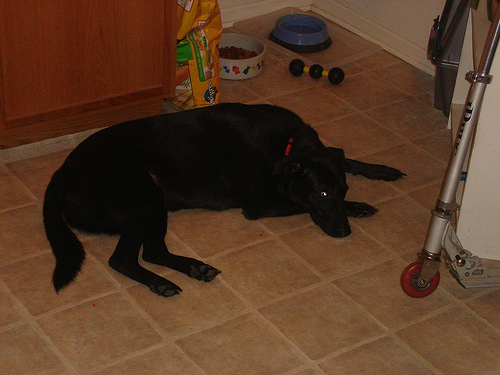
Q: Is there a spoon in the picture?
A: No, there are no spoons.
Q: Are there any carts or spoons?
A: No, there are no spoons or carts.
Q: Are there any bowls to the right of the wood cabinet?
A: Yes, there is a bowl to the right of the cabinet.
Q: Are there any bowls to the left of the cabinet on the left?
A: No, the bowl is to the right of the cabinet.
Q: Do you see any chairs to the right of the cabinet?
A: No, there is a bowl to the right of the cabinet.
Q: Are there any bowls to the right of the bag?
A: Yes, there is a bowl to the right of the bag.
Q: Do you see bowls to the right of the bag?
A: Yes, there is a bowl to the right of the bag.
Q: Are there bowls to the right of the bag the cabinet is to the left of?
A: Yes, there is a bowl to the right of the bag.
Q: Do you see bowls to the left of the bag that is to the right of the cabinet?
A: No, the bowl is to the right of the bag.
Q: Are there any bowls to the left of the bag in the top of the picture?
A: No, the bowl is to the right of the bag.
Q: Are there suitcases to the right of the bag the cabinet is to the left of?
A: No, there is a bowl to the right of the bag.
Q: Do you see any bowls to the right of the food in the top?
A: Yes, there is a bowl to the right of the food.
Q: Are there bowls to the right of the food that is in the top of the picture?
A: Yes, there is a bowl to the right of the food.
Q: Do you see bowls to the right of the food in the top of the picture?
A: Yes, there is a bowl to the right of the food.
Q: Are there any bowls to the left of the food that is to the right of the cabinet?
A: No, the bowl is to the right of the food.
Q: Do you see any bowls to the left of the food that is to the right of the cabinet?
A: No, the bowl is to the right of the food.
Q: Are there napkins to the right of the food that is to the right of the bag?
A: No, there is a bowl to the right of the food.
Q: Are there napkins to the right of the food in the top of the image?
A: No, there is a bowl to the right of the food.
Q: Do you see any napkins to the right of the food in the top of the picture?
A: No, there is a bowl to the right of the food.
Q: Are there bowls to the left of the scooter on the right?
A: Yes, there is a bowl to the left of the scooter.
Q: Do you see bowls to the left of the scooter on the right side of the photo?
A: Yes, there is a bowl to the left of the scooter.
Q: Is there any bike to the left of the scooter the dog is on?
A: No, there is a bowl to the left of the scooter.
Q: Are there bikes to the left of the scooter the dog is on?
A: No, there is a bowl to the left of the scooter.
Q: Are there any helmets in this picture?
A: No, there are no helmets.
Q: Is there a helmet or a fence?
A: No, there are no helmets or fences.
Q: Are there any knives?
A: No, there are no knives.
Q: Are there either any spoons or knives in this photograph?
A: No, there are no knives or spoons.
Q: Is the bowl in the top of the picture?
A: Yes, the bowl is in the top of the image.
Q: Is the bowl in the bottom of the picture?
A: No, the bowl is in the top of the image.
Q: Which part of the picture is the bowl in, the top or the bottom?
A: The bowl is in the top of the image.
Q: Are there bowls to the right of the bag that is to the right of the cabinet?
A: Yes, there is a bowl to the right of the bag.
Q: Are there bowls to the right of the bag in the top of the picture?
A: Yes, there is a bowl to the right of the bag.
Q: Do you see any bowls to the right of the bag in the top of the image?
A: Yes, there is a bowl to the right of the bag.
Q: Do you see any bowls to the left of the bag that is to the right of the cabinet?
A: No, the bowl is to the right of the bag.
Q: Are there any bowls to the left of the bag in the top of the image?
A: No, the bowl is to the right of the bag.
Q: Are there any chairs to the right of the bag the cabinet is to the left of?
A: No, there is a bowl to the right of the bag.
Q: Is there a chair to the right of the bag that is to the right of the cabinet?
A: No, there is a bowl to the right of the bag.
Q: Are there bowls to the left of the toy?
A: Yes, there is a bowl to the left of the toy.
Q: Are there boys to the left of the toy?
A: No, there is a bowl to the left of the toy.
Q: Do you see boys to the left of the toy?
A: No, there is a bowl to the left of the toy.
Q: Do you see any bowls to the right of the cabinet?
A: Yes, there is a bowl to the right of the cabinet.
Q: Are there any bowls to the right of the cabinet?
A: Yes, there is a bowl to the right of the cabinet.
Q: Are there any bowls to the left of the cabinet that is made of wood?
A: No, the bowl is to the right of the cabinet.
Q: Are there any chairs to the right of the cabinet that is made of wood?
A: No, there is a bowl to the right of the cabinet.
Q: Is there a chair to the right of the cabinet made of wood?
A: No, there is a bowl to the right of the cabinet.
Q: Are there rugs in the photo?
A: No, there are no rugs.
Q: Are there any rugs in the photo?
A: No, there are no rugs.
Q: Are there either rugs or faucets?
A: No, there are no rugs or faucets.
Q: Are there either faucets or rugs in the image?
A: No, there are no rugs or faucets.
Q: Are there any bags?
A: Yes, there is a bag.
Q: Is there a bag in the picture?
A: Yes, there is a bag.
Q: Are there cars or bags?
A: Yes, there is a bag.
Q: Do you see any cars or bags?
A: Yes, there is a bag.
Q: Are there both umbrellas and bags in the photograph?
A: No, there is a bag but no umbrellas.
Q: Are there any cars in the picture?
A: No, there are no cars.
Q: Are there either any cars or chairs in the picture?
A: No, there are no cars or chairs.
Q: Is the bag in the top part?
A: Yes, the bag is in the top of the image.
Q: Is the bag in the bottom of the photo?
A: No, the bag is in the top of the image.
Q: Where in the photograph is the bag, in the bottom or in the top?
A: The bag is in the top of the image.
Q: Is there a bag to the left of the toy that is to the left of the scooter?
A: Yes, there is a bag to the left of the toy.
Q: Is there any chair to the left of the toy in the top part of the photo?
A: No, there is a bag to the left of the toy.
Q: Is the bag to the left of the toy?
A: Yes, the bag is to the left of the toy.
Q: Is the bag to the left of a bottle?
A: No, the bag is to the left of the toy.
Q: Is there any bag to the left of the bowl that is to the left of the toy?
A: Yes, there is a bag to the left of the bowl.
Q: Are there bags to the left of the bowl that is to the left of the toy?
A: Yes, there is a bag to the left of the bowl.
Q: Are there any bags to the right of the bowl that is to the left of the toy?
A: No, the bag is to the left of the bowl.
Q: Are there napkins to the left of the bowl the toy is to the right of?
A: No, there is a bag to the left of the bowl.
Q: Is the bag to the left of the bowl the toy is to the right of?
A: Yes, the bag is to the left of the bowl.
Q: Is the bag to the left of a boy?
A: No, the bag is to the left of the bowl.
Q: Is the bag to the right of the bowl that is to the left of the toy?
A: No, the bag is to the left of the bowl.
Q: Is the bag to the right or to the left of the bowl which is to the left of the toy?
A: The bag is to the left of the bowl.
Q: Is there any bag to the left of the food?
A: Yes, there is a bag to the left of the food.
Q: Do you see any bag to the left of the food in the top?
A: Yes, there is a bag to the left of the food.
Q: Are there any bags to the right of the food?
A: No, the bag is to the left of the food.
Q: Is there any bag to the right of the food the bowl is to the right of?
A: No, the bag is to the left of the food.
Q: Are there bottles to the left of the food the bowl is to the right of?
A: No, there is a bag to the left of the food.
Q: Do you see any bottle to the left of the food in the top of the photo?
A: No, there is a bag to the left of the food.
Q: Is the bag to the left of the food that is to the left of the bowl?
A: Yes, the bag is to the left of the food.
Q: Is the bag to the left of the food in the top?
A: Yes, the bag is to the left of the food.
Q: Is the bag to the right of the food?
A: No, the bag is to the left of the food.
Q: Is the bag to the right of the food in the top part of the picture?
A: No, the bag is to the left of the food.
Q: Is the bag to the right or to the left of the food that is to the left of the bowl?
A: The bag is to the left of the food.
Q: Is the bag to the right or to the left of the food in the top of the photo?
A: The bag is to the left of the food.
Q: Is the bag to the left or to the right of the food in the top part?
A: The bag is to the left of the food.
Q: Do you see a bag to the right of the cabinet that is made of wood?
A: Yes, there is a bag to the right of the cabinet.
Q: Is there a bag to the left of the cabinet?
A: No, the bag is to the right of the cabinet.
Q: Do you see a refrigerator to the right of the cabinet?
A: No, there is a bag to the right of the cabinet.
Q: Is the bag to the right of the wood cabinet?
A: Yes, the bag is to the right of the cabinet.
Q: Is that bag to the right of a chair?
A: No, the bag is to the right of the cabinet.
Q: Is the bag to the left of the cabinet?
A: No, the bag is to the right of the cabinet.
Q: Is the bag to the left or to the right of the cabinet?
A: The bag is to the right of the cabinet.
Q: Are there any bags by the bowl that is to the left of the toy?
A: Yes, there is a bag by the bowl.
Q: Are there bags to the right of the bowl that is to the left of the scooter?
A: No, the bag is to the left of the bowl.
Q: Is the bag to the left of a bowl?
A: Yes, the bag is to the left of a bowl.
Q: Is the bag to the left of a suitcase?
A: No, the bag is to the left of a bowl.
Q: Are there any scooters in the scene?
A: Yes, there is a scooter.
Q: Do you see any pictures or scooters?
A: Yes, there is a scooter.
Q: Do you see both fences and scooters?
A: No, there is a scooter but no fences.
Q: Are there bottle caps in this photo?
A: No, there are no bottle caps.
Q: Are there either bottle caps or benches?
A: No, there are no bottle caps or benches.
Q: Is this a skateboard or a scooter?
A: This is a scooter.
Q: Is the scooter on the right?
A: Yes, the scooter is on the right of the image.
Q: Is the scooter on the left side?
A: No, the scooter is on the right of the image.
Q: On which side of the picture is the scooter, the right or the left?
A: The scooter is on the right of the image.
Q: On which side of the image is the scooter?
A: The scooter is on the right of the image.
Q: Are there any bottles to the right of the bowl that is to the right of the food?
A: No, there is a scooter to the right of the bowl.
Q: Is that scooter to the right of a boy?
A: No, the scooter is to the right of the bowl.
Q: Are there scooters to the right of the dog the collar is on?
A: Yes, there is a scooter to the right of the dog.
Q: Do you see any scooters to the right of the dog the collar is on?
A: Yes, there is a scooter to the right of the dog.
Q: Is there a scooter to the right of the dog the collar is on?
A: Yes, there is a scooter to the right of the dog.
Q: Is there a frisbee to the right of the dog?
A: No, there is a scooter to the right of the dog.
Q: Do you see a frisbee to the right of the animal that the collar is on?
A: No, there is a scooter to the right of the dog.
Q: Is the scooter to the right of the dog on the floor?
A: Yes, the scooter is to the right of the dog.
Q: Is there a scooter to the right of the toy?
A: Yes, there is a scooter to the right of the toy.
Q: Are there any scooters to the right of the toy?
A: Yes, there is a scooter to the right of the toy.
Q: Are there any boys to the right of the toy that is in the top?
A: No, there is a scooter to the right of the toy.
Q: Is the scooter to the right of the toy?
A: Yes, the scooter is to the right of the toy.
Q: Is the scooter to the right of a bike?
A: No, the scooter is to the right of the toy.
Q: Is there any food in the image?
A: Yes, there is food.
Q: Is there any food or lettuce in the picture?
A: Yes, there is food.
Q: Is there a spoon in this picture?
A: No, there are no spoons.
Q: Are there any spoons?
A: No, there are no spoons.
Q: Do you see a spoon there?
A: No, there are no spoons.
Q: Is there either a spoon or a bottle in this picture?
A: No, there are no spoons or bottles.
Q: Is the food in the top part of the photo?
A: Yes, the food is in the top of the image.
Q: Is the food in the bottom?
A: No, the food is in the top of the image.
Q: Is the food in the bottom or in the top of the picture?
A: The food is in the top of the image.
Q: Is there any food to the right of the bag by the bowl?
A: Yes, there is food to the right of the bag.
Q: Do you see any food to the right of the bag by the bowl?
A: Yes, there is food to the right of the bag.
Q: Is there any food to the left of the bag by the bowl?
A: No, the food is to the right of the bag.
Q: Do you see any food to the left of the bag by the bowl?
A: No, the food is to the right of the bag.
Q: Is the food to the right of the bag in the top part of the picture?
A: Yes, the food is to the right of the bag.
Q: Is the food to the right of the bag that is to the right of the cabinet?
A: Yes, the food is to the right of the bag.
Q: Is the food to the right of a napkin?
A: No, the food is to the right of the bag.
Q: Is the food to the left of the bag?
A: No, the food is to the right of the bag.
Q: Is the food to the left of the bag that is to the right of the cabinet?
A: No, the food is to the right of the bag.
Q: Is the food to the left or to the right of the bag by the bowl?
A: The food is to the right of the bag.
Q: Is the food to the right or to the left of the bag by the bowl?
A: The food is to the right of the bag.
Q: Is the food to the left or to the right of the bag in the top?
A: The food is to the right of the bag.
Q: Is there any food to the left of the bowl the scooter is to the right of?
A: Yes, there is food to the left of the bowl.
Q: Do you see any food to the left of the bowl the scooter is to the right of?
A: Yes, there is food to the left of the bowl.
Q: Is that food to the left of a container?
A: No, the food is to the left of the bowl.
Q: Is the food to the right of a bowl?
A: No, the food is to the left of a bowl.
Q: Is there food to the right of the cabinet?
A: Yes, there is food to the right of the cabinet.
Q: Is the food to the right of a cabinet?
A: Yes, the food is to the right of a cabinet.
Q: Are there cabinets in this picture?
A: Yes, there is a cabinet.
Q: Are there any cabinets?
A: Yes, there is a cabinet.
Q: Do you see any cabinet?
A: Yes, there is a cabinet.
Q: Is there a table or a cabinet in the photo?
A: Yes, there is a cabinet.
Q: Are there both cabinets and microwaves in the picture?
A: No, there is a cabinet but no microwaves.